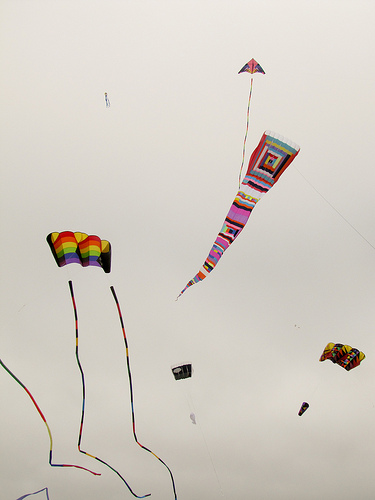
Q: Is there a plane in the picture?
A: No, there are no airplanes.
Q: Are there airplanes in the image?
A: No, there are no airplanes.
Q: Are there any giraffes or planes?
A: No, there are no planes or giraffes.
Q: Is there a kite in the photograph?
A: Yes, there is a kite.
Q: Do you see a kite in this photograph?
A: Yes, there is a kite.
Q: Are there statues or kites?
A: Yes, there is a kite.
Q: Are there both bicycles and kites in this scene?
A: No, there is a kite but no bicycles.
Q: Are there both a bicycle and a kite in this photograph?
A: No, there is a kite but no bicycles.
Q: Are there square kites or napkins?
A: Yes, there is a square kite.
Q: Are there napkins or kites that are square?
A: Yes, the kite is square.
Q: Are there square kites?
A: Yes, there is a square kite.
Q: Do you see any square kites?
A: Yes, there is a square kite.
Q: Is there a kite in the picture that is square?
A: Yes, there is a kite that is square.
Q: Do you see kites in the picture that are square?
A: Yes, there is a kite that is square.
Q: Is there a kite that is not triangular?
A: Yes, there is a square kite.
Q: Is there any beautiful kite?
A: Yes, there is a beautiful kite.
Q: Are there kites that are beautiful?
A: Yes, there is a kite that is beautiful.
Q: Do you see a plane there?
A: No, there are no airplanes.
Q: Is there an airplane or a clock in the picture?
A: No, there are no airplanes or clocks.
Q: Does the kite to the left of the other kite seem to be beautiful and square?
A: Yes, the kite is beautiful and square.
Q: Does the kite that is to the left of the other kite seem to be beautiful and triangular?
A: No, the kite is beautiful but square.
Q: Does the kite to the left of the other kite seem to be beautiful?
A: Yes, the kite is beautiful.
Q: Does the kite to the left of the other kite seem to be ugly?
A: No, the kite is beautiful.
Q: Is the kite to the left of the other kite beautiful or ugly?
A: The kite is beautiful.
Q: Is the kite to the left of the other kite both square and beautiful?
A: Yes, the kite is square and beautiful.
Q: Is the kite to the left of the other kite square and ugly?
A: No, the kite is square but beautiful.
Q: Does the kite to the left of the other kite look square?
A: Yes, the kite is square.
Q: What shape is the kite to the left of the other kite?
A: The kite is square.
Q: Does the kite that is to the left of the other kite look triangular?
A: No, the kite is square.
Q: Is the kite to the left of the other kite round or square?
A: The kite is square.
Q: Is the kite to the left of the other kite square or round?
A: The kite is square.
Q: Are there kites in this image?
A: Yes, there is a kite.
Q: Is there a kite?
A: Yes, there is a kite.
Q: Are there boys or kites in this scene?
A: Yes, there is a kite.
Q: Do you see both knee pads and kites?
A: No, there is a kite but no knee pads.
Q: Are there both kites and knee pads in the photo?
A: No, there is a kite but no knee pads.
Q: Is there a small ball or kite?
A: Yes, there is a small kite.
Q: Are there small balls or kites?
A: Yes, there is a small kite.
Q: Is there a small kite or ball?
A: Yes, there is a small kite.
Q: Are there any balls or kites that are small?
A: Yes, the kite is small.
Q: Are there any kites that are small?
A: Yes, there is a kite that is small.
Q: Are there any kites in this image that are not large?
A: Yes, there is a small kite.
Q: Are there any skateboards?
A: No, there are no skateboards.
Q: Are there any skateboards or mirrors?
A: No, there are no skateboards or mirrors.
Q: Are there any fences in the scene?
A: No, there are no fences.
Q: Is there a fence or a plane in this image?
A: No, there are no fences or airplanes.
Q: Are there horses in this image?
A: No, there are no horses.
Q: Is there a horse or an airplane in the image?
A: No, there are no horses or airplanes.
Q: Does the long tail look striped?
A: Yes, the tail is striped.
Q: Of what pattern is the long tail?
A: The tail is striped.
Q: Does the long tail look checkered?
A: No, the tail is striped.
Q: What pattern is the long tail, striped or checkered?
A: The tail is striped.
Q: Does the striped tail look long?
A: Yes, the tail is long.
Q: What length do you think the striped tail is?
A: The tail is long.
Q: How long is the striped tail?
A: The tail is long.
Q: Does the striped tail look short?
A: No, the tail is long.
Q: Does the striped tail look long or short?
A: The tail is long.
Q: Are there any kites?
A: Yes, there is a kite.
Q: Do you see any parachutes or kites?
A: Yes, there is a kite.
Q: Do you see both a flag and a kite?
A: No, there is a kite but no flags.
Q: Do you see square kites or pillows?
A: Yes, there is a square kite.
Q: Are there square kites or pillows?
A: Yes, there is a square kite.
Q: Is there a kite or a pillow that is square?
A: Yes, the kite is square.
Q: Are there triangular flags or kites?
A: Yes, there is a triangular kite.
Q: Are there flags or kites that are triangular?
A: Yes, the kite is triangular.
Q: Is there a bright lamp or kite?
A: Yes, there is a bright kite.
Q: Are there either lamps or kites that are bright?
A: Yes, the kite is bright.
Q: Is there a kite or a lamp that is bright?
A: Yes, the kite is bright.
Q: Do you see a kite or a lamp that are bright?
A: Yes, the kite is bright.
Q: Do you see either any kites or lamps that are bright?
A: Yes, the kite is bright.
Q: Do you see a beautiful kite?
A: Yes, there is a beautiful kite.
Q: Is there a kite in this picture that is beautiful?
A: Yes, there is a kite that is beautiful.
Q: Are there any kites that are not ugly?
A: Yes, there is an beautiful kite.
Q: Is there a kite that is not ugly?
A: Yes, there is an beautiful kite.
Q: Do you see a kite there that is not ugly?
A: Yes, there is an beautiful kite.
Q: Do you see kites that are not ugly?
A: Yes, there is an beautiful kite.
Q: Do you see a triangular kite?
A: Yes, there is a triangular kite.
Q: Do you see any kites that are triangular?
A: Yes, there is a kite that is triangular.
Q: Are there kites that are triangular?
A: Yes, there is a kite that is triangular.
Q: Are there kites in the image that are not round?
A: Yes, there is a triangular kite.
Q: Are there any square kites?
A: Yes, there is a square kite.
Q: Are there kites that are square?
A: Yes, there is a kite that is square.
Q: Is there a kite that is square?
A: Yes, there is a kite that is square.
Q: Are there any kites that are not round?
A: Yes, there is a square kite.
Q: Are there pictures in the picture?
A: No, there are no pictures.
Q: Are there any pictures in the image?
A: No, there are no pictures.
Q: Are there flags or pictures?
A: No, there are no pictures or flags.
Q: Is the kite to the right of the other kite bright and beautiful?
A: Yes, the kite is bright and beautiful.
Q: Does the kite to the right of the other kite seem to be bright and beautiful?
A: Yes, the kite is bright and beautiful.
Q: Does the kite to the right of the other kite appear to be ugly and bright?
A: No, the kite is bright but beautiful.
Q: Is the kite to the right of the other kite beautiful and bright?
A: Yes, the kite is beautiful and bright.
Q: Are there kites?
A: Yes, there is a kite.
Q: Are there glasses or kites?
A: Yes, there is a kite.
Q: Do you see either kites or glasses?
A: Yes, there is a kite.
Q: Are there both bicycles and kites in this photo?
A: No, there is a kite but no bicycles.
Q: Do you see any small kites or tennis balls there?
A: Yes, there is a small kite.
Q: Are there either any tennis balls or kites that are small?
A: Yes, the kite is small.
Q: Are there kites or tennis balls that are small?
A: Yes, the kite is small.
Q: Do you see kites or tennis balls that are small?
A: Yes, the kite is small.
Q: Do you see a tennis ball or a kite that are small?
A: Yes, the kite is small.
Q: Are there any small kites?
A: Yes, there is a small kite.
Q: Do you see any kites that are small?
A: Yes, there is a kite that is small.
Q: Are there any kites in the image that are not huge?
A: Yes, there is a small kite.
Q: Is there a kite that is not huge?
A: Yes, there is a small kite.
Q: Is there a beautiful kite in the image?
A: Yes, there is a beautiful kite.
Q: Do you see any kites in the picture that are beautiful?
A: Yes, there is a kite that is beautiful.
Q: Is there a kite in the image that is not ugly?
A: Yes, there is an beautiful kite.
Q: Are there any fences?
A: No, there are no fences.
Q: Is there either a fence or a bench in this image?
A: No, there are no fences or benches.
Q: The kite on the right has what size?
A: The kite is small.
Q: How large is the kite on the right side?
A: The kite is small.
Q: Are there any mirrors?
A: No, there are no mirrors.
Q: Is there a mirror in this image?
A: No, there are no mirrors.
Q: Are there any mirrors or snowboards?
A: No, there are no mirrors or snowboards.